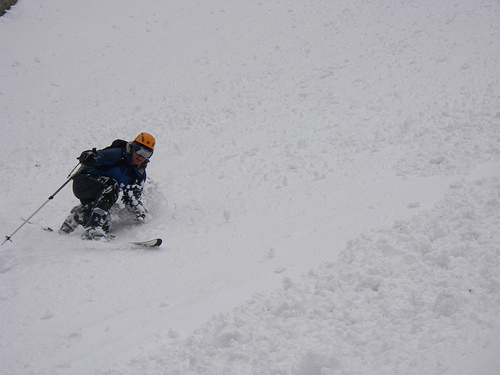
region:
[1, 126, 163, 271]
man leaning on skis in snow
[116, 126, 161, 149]
orange hat on skier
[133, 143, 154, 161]
goggles on skier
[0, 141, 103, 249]
ski pole in skier's hand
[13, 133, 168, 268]
person skiing in white snow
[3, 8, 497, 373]
snow covered mountain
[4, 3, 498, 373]
fluffy white snow on ground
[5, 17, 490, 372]
a scene outside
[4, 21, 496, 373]
a scene during the day time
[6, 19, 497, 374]
a scene in a hillside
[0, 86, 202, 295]
a skier making a turn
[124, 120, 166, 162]
a yellow helmet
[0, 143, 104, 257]
a black ski pole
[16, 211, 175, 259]
a white and black ski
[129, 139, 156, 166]
a pair of goggles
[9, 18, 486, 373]
some snow on the ground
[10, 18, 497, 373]
a place to do some skiing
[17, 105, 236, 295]
a person with the snow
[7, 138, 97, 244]
a person holding snow pole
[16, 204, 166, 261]
snowboard in the snow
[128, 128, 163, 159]
a person wearing cap on his head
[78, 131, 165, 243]
a person wearing snowsuit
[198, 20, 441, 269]
a place full of snow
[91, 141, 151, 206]
a person wearing blue color jacket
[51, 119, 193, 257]
a person with snow pole and snow board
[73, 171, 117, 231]
black color pant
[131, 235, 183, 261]
white and black color snowboard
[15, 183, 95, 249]
this is a pole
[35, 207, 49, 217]
this is a ski pole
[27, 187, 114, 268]
the pole is metal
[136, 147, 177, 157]
this is a helmet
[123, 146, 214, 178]
this is a pair of goggles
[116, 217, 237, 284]
this is a ski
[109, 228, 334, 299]
the ski is white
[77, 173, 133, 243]
this is a pair of pants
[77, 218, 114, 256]
this is a shoe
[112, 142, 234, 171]
this is a head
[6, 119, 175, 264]
skier coming down the mountain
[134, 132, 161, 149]
yellow helmet skier is wearing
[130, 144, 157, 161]
snow goggles the skier is wearing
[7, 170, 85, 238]
black ski pole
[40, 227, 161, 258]
skis the skier is wearing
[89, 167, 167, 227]
snow kicked up my skier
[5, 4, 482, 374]
mountainside the skier is coming down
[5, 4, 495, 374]
snow covered mountainside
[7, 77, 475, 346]
tracks in the snow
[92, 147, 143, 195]
blue jacket the skier is wearing